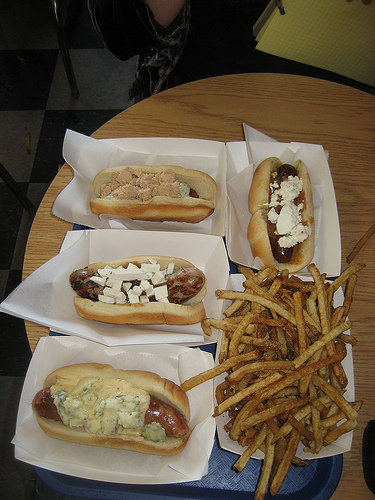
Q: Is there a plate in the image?
A: No, there are no plates.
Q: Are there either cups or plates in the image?
A: No, there are no plates or cups.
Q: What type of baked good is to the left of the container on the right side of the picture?
A: The food is a bun.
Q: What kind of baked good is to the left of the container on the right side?
A: The food is a bun.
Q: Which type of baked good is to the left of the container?
A: The food is a bun.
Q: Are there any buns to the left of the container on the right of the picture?
A: Yes, there is a bun to the left of the container.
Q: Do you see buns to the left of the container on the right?
A: Yes, there is a bun to the left of the container.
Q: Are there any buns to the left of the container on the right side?
A: Yes, there is a bun to the left of the container.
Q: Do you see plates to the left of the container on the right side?
A: No, there is a bun to the left of the container.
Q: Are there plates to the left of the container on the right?
A: No, there is a bun to the left of the container.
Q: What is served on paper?
A: The bun is served on paper.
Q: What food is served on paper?
A: The food is a bun.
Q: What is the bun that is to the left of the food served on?
A: The bun is served on paper.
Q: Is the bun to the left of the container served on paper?
A: Yes, the bun is served on paper.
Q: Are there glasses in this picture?
A: No, there are no glasses.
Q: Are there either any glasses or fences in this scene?
A: No, there are no glasses or fences.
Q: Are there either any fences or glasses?
A: No, there are no glasses or fences.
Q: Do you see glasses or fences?
A: No, there are no glasses or fences.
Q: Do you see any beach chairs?
A: No, there are no beach chairs.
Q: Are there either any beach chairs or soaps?
A: No, there are no beach chairs or soaps.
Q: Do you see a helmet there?
A: No, there are no helmets.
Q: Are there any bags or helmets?
A: No, there are no helmets or bags.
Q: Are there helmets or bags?
A: No, there are no helmets or bags.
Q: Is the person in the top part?
A: Yes, the person is in the top of the image.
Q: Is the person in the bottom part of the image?
A: No, the person is in the top of the image.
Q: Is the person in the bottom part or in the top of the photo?
A: The person is in the top of the image.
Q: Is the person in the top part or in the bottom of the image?
A: The person is in the top of the image.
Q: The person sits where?
A: The person sits at the table.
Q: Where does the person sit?
A: The person sits at the table.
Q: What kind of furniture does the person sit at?
A: The person sits at the table.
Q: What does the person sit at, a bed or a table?
A: The person sits at a table.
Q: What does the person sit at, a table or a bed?
A: The person sits at a table.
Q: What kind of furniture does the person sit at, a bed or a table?
A: The person sits at a table.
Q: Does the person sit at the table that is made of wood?
A: Yes, the person sits at the table.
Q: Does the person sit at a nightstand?
A: No, the person sits at the table.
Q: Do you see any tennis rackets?
A: No, there are no tennis rackets.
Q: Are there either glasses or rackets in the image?
A: No, there are no rackets or glasses.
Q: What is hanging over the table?
A: The tray is hanging over the table.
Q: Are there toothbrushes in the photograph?
A: No, there are no toothbrushes.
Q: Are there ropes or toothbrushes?
A: No, there are no toothbrushes or ropes.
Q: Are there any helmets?
A: No, there are no helmets.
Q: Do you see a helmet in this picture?
A: No, there are no helmets.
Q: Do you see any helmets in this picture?
A: No, there are no helmets.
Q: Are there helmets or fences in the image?
A: No, there are no helmets or fences.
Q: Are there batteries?
A: No, there are no batteries.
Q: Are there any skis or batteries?
A: No, there are no batteries or skis.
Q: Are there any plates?
A: No, there are no plates.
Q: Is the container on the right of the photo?
A: Yes, the container is on the right of the image.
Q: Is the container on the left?
A: No, the container is on the right of the image.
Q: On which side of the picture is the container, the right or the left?
A: The container is on the right of the image.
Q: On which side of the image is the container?
A: The container is on the right of the image.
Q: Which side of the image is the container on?
A: The container is on the right of the image.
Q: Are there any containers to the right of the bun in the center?
A: Yes, there is a container to the right of the bun.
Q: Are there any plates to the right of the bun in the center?
A: No, there is a container to the right of the bun.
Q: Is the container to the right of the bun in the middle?
A: Yes, the container is to the right of the bun.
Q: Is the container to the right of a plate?
A: No, the container is to the right of the bun.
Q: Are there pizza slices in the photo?
A: No, there are no pizza slices.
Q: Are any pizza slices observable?
A: No, there are no pizza slices.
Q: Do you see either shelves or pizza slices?
A: No, there are no pizza slices or shelves.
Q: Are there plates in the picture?
A: No, there are no plates.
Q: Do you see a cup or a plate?
A: No, there are no plates or cups.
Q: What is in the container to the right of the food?
A: The bun is in the container.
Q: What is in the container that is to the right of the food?
A: The bun is in the container.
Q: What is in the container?
A: The bun is in the container.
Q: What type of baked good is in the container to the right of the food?
A: The food is a bun.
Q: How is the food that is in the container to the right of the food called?
A: The food is a bun.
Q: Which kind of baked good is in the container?
A: The food is a bun.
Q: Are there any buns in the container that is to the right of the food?
A: Yes, there is a bun in the container.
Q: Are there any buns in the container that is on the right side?
A: Yes, there is a bun in the container.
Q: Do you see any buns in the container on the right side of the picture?
A: Yes, there is a bun in the container.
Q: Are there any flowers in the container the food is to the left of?
A: No, there is a bun in the container.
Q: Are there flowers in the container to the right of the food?
A: No, there is a bun in the container.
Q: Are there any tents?
A: No, there are no tents.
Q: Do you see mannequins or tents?
A: No, there are no tents or mannequins.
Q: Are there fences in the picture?
A: No, there are no fences.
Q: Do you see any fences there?
A: No, there are no fences.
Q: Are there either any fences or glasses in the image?
A: No, there are no fences or glasses.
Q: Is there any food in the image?
A: Yes, there is food.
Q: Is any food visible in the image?
A: Yes, there is food.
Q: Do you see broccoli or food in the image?
A: Yes, there is food.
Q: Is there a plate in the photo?
A: No, there are no plates.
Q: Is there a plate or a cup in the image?
A: No, there are no plates or cups.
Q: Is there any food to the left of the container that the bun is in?
A: Yes, there is food to the left of the container.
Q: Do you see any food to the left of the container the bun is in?
A: Yes, there is food to the left of the container.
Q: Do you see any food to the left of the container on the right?
A: Yes, there is food to the left of the container.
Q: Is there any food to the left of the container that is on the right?
A: Yes, there is food to the left of the container.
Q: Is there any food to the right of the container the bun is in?
A: No, the food is to the left of the container.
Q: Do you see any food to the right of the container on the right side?
A: No, the food is to the left of the container.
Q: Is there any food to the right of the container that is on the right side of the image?
A: No, the food is to the left of the container.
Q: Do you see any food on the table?
A: Yes, there is food on the table.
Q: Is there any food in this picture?
A: Yes, there is food.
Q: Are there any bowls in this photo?
A: No, there are no bowls.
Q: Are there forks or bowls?
A: No, there are no bowls or forks.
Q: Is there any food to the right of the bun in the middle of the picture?
A: Yes, there is food to the right of the bun.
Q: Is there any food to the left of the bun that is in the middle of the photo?
A: No, the food is to the right of the bun.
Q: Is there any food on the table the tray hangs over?
A: Yes, there is food on the table.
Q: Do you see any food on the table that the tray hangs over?
A: Yes, there is food on the table.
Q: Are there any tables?
A: Yes, there is a table.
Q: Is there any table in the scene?
A: Yes, there is a table.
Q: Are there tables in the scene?
A: Yes, there is a table.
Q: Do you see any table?
A: Yes, there is a table.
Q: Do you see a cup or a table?
A: Yes, there is a table.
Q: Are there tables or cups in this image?
A: Yes, there is a table.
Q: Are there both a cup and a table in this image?
A: No, there is a table but no cups.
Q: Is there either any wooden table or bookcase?
A: Yes, there is a wood table.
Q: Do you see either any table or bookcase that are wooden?
A: Yes, the table is wooden.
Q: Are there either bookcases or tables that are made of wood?
A: Yes, the table is made of wood.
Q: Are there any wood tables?
A: Yes, there is a wood table.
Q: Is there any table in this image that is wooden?
A: Yes, there is a table that is wooden.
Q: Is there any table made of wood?
A: Yes, there is a table that is made of wood.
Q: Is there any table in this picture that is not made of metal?
A: Yes, there is a table that is made of wood.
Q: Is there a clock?
A: No, there are no clocks.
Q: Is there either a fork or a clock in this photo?
A: No, there are no clocks or forks.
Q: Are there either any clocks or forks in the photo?
A: No, there are no clocks or forks.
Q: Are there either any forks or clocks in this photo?
A: No, there are no clocks or forks.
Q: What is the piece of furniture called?
A: The piece of furniture is a table.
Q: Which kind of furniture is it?
A: The piece of furniture is a table.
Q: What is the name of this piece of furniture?
A: That is a table.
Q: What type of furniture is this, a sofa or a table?
A: That is a table.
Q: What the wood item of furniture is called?
A: The piece of furniture is a table.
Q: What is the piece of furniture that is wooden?
A: The piece of furniture is a table.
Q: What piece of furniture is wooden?
A: The piece of furniture is a table.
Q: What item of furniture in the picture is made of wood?
A: The piece of furniture is a table.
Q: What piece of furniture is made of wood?
A: The piece of furniture is a table.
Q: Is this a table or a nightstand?
A: This is a table.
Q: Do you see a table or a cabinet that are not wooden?
A: No, there is a table but it is wooden.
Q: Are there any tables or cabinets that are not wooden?
A: No, there is a table but it is wooden.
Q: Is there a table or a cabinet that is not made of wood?
A: No, there is a table but it is made of wood.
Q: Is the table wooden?
A: Yes, the table is wooden.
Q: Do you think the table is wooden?
A: Yes, the table is wooden.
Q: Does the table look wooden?
A: Yes, the table is wooden.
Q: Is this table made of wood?
A: Yes, the table is made of wood.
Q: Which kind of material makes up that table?
A: The table is made of wood.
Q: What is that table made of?
A: The table is made of wood.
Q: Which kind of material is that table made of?
A: The table is made of wood.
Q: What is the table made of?
A: The table is made of wood.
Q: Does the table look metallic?
A: No, the table is wooden.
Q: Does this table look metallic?
A: No, the table is wooden.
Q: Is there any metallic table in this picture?
A: No, there is a table but it is wooden.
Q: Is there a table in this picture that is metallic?
A: No, there is a table but it is wooden.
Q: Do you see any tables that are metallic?
A: No, there is a table but it is wooden.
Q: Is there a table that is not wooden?
A: No, there is a table but it is wooden.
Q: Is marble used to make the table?
A: No, the table is made of wood.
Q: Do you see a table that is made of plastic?
A: No, there is a table but it is made of wood.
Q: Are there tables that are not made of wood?
A: No, there is a table but it is made of wood.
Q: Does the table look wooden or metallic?
A: The table is wooden.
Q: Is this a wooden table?
A: Yes, this is a wooden table.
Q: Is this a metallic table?
A: No, this is a wooden table.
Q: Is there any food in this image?
A: Yes, there is food.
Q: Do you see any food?
A: Yes, there is food.